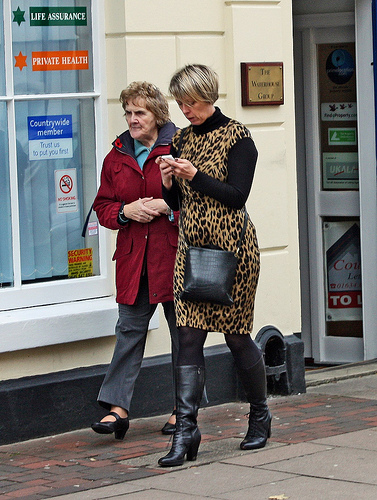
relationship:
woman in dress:
[162, 66, 269, 443] [184, 145, 226, 308]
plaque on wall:
[243, 63, 303, 112] [265, 17, 271, 29]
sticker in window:
[16, 5, 96, 27] [10, 46, 95, 278]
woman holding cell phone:
[162, 66, 269, 443] [155, 149, 173, 178]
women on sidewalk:
[96, 88, 269, 385] [284, 408, 331, 479]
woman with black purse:
[162, 66, 269, 443] [165, 238, 236, 306]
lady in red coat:
[101, 86, 178, 411] [93, 121, 174, 272]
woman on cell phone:
[162, 66, 269, 443] [155, 149, 173, 178]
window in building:
[10, 46, 95, 278] [17, 6, 351, 149]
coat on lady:
[93, 121, 174, 272] [101, 86, 178, 411]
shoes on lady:
[54, 402, 204, 433] [101, 86, 178, 411]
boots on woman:
[172, 358, 299, 446] [162, 66, 269, 443]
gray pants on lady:
[111, 310, 198, 402] [101, 86, 178, 411]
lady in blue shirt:
[101, 86, 178, 411] [130, 140, 151, 165]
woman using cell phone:
[162, 66, 269, 443] [155, 149, 173, 178]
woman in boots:
[162, 66, 269, 443] [172, 358, 299, 446]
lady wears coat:
[101, 86, 178, 411] [93, 121, 174, 272]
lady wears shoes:
[101, 86, 178, 411] [54, 402, 204, 433]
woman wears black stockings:
[162, 66, 269, 443] [180, 323, 297, 370]